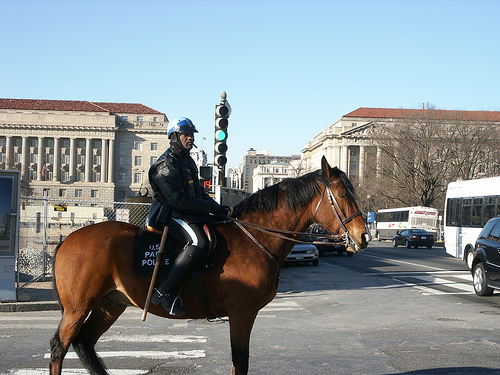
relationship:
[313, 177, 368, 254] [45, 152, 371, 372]
bridle on a horse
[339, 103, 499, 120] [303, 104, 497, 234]
roof on a building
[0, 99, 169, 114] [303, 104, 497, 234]
roof on a building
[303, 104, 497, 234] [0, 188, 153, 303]
building near a fence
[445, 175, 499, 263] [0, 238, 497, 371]
bus on street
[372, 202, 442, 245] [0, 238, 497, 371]
bus on street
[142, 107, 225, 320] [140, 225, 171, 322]
officer has a baton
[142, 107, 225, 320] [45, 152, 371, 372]
officer on a horse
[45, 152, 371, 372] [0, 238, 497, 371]
horse in street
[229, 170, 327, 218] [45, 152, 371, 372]
mane on horse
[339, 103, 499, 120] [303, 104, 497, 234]
roof on building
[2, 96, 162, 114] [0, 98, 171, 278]
roof on building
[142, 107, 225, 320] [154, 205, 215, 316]
officer wearing pants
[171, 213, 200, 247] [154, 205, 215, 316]
stripe on pants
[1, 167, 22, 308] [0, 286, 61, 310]
box on sidewalk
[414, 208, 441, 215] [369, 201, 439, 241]
stripe on bus